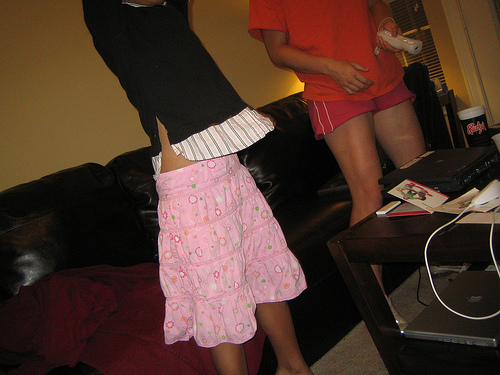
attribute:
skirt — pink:
[153, 151, 308, 347]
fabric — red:
[2, 264, 266, 374]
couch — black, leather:
[6, 92, 453, 373]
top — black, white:
[81, 1, 275, 173]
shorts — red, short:
[304, 79, 416, 141]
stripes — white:
[312, 101, 334, 135]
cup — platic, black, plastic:
[456, 103, 490, 145]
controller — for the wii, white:
[375, 29, 420, 55]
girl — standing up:
[83, 2, 314, 374]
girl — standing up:
[247, 3, 425, 331]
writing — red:
[465, 120, 487, 137]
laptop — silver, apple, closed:
[402, 271, 499, 348]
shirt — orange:
[248, 2, 406, 103]